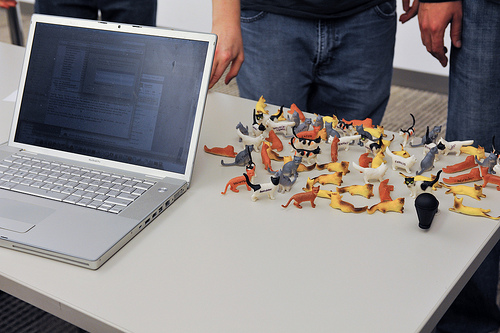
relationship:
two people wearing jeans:
[213, 5, 495, 136] [237, 3, 404, 106]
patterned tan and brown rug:
[423, 111, 444, 121] [399, 85, 448, 134]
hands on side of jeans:
[202, 8, 239, 81] [230, 5, 397, 127]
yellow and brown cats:
[357, 189, 367, 197] [287, 178, 337, 216]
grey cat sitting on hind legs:
[279, 160, 298, 185] [294, 196, 326, 213]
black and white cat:
[423, 196, 433, 221] [250, 140, 340, 201]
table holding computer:
[7, 41, 483, 322] [0, 13, 221, 270]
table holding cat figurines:
[7, 41, 483, 322] [202, 95, 500, 228]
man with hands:
[208, 0, 393, 122] [202, 24, 241, 88]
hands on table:
[202, 24, 241, 88] [7, 41, 483, 322]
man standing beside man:
[208, 0, 393, 122] [412, 4, 484, 139]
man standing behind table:
[208, 0, 393, 122] [7, 41, 483, 322]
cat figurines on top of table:
[205, 92, 477, 240] [7, 41, 483, 322]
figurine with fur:
[234, 128, 267, 150] [231, 126, 271, 148]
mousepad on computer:
[0, 194, 55, 239] [0, 13, 216, 271]